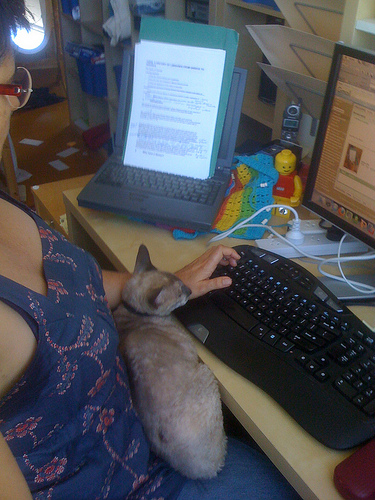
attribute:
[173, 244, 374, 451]
keyboard — black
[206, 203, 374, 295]
power cord — plugged in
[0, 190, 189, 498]
shirt — floral, blue, red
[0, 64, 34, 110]
glasses — red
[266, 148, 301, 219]
lego toy — yellow, large, plastic, red, small, ellow ad red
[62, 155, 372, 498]
desk — wooden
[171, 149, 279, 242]
crochet — colored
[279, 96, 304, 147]
cordless phone — black, gray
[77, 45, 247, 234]
laptop — open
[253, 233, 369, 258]
power strip — white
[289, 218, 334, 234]
power strip — white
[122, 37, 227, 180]
papers — black ad white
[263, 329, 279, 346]
key — black ad white, black, white